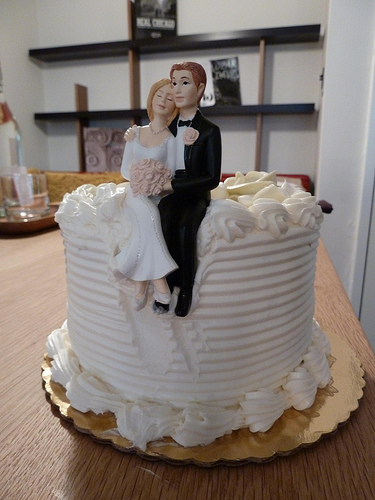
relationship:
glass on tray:
[0, 160, 51, 201] [0, 213, 70, 242]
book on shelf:
[206, 50, 250, 108] [126, 4, 375, 132]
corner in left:
[308, 0, 369, 29] [14, 0, 80, 124]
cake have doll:
[43, 166, 334, 455] [112, 61, 221, 317]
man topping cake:
[170, 62, 235, 242] [15, 154, 360, 456]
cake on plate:
[15, 154, 360, 456] [61, 321, 373, 458]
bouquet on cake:
[124, 154, 217, 205] [15, 154, 360, 456]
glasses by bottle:
[1, 125, 92, 240] [7, 91, 26, 171]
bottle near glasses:
[7, 91, 26, 171] [1, 125, 92, 240]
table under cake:
[8, 256, 69, 484] [15, 154, 360, 456]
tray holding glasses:
[0, 213, 70, 242] [1, 125, 92, 240]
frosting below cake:
[61, 321, 373, 458] [15, 154, 360, 456]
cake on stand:
[15, 154, 360, 456] [235, 406, 358, 441]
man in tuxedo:
[170, 62, 235, 242] [163, 129, 246, 246]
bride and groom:
[106, 115, 160, 310] [166, 62, 210, 298]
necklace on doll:
[141, 118, 180, 147] [113, 109, 212, 353]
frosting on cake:
[54, 160, 243, 359] [15, 154, 360, 456]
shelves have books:
[33, 24, 331, 71] [117, 4, 270, 128]